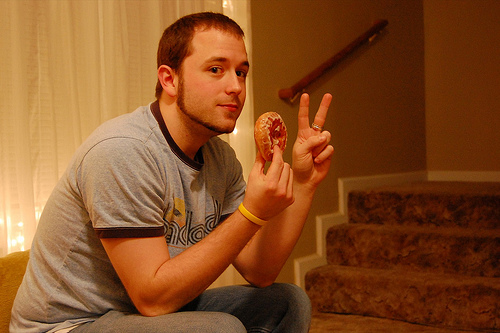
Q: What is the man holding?
A: A donut.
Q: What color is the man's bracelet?
A: Yellow.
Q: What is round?
A: Donut.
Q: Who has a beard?
A: The man.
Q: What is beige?
A: Walls.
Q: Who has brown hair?
A: A man.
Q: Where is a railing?
A: On the wall.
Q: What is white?
A: Curtains.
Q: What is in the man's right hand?
A: Donut.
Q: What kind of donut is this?
A: Glazed cake donut.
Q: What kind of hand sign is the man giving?
A: Peace.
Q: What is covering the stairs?
A: Carpet.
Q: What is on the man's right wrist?
A: Yellow bracelet.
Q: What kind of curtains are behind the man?
A: Sheer.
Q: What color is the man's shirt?
A: Heather grey.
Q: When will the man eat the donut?
A: Soon.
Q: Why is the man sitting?
A: To eat.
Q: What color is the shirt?
A: Grey.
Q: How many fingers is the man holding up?
A: 2.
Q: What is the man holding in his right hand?
A: Donut.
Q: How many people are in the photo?
A: 1.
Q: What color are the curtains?
A: White.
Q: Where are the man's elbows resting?
A: On his thighs.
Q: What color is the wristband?
A: Yellow.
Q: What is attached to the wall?
A: Railing.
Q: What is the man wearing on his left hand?
A: Ring.